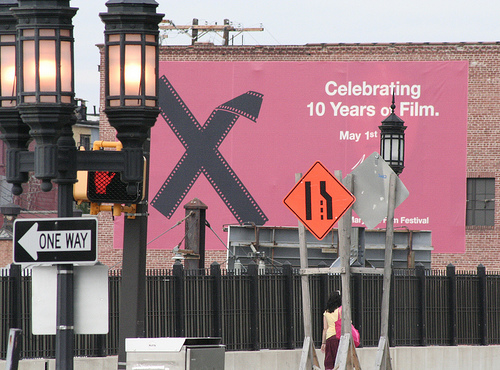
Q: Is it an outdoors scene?
A: Yes, it is outdoors.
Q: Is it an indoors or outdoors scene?
A: It is outdoors.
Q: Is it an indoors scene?
A: No, it is outdoors.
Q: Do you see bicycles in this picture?
A: No, there are no bicycles.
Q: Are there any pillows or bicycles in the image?
A: No, there are no bicycles or pillows.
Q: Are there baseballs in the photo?
A: No, there are no baseballs.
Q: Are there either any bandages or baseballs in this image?
A: No, there are no baseballs or bandages.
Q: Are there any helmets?
A: No, there are no helmets.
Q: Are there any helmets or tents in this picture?
A: No, there are no helmets or tents.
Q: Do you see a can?
A: No, there are no cans.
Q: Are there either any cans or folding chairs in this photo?
A: No, there are no cans or folding chairs.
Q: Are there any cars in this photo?
A: No, there are no cars.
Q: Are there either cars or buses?
A: No, there are no cars or buses.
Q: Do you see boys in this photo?
A: No, there are no boys.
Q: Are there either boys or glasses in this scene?
A: No, there are no boys or glasses.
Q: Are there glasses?
A: No, there are no glasses.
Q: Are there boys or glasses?
A: No, there are no glasses or boys.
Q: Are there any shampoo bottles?
A: No, there are no shampoo bottles.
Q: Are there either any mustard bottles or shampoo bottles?
A: No, there are no shampoo bottles or mustard bottles.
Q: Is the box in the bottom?
A: Yes, the box is in the bottom of the image.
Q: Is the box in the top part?
A: No, the box is in the bottom of the image.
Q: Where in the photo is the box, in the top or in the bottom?
A: The box is in the bottom of the image.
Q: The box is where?
A: The box is on the street.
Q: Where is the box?
A: The box is on the street.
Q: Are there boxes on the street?
A: Yes, there is a box on the street.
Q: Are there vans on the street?
A: No, there is a box on the street.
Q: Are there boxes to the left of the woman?
A: Yes, there is a box to the left of the woman.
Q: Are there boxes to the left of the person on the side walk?
A: Yes, there is a box to the left of the woman.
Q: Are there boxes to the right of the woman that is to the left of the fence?
A: No, the box is to the left of the woman.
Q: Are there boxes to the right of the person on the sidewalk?
A: No, the box is to the left of the woman.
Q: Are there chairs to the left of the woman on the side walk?
A: No, there is a box to the left of the woman.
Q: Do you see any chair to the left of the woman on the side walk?
A: No, there is a box to the left of the woman.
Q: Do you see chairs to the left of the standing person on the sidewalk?
A: No, there is a box to the left of the woman.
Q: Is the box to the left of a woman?
A: Yes, the box is to the left of a woman.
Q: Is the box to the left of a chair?
A: No, the box is to the left of a woman.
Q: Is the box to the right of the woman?
A: No, the box is to the left of the woman.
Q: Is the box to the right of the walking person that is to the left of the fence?
A: No, the box is to the left of the woman.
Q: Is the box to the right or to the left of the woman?
A: The box is to the left of the woman.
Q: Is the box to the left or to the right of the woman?
A: The box is to the left of the woman.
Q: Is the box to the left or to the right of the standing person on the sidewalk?
A: The box is to the left of the woman.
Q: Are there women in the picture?
A: Yes, there is a woman.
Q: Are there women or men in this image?
A: Yes, there is a woman.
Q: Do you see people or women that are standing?
A: Yes, the woman is standing.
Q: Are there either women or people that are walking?
A: Yes, the woman is walking.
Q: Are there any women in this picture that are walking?
A: Yes, there is a woman that is walking.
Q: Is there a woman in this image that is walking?
A: Yes, there is a woman that is walking.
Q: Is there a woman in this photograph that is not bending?
A: Yes, there is a woman that is walking.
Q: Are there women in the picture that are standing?
A: Yes, there is a woman that is standing.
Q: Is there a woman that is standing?
A: Yes, there is a woman that is standing.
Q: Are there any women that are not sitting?
A: Yes, there is a woman that is standing.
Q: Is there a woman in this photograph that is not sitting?
A: Yes, there is a woman that is standing.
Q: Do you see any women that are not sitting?
A: Yes, there is a woman that is standing .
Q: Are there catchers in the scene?
A: No, there are no catchers.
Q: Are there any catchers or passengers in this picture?
A: No, there are no catchers or passengers.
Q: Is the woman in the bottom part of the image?
A: Yes, the woman is in the bottom of the image.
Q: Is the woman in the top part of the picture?
A: No, the woman is in the bottom of the image.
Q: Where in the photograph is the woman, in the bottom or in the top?
A: The woman is in the bottom of the image.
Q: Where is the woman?
A: The woman is on the sidewalk.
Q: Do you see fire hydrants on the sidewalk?
A: No, there is a woman on the sidewalk.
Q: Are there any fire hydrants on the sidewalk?
A: No, there is a woman on the sidewalk.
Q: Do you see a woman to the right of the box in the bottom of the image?
A: Yes, there is a woman to the right of the box.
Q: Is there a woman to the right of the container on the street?
A: Yes, there is a woman to the right of the box.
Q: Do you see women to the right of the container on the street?
A: Yes, there is a woman to the right of the box.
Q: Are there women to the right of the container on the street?
A: Yes, there is a woman to the right of the box.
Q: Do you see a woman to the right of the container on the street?
A: Yes, there is a woman to the right of the box.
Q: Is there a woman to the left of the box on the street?
A: No, the woman is to the right of the box.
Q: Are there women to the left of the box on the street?
A: No, the woman is to the right of the box.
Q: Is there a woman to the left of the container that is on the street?
A: No, the woman is to the right of the box.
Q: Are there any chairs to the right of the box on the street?
A: No, there is a woman to the right of the box.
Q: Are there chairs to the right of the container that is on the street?
A: No, there is a woman to the right of the box.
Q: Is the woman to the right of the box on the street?
A: Yes, the woman is to the right of the box.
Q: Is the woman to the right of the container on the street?
A: Yes, the woman is to the right of the box.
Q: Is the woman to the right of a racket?
A: No, the woman is to the right of the box.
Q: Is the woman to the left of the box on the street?
A: No, the woman is to the right of the box.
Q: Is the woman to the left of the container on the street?
A: No, the woman is to the right of the box.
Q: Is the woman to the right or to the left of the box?
A: The woman is to the right of the box.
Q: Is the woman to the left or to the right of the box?
A: The woman is to the right of the box.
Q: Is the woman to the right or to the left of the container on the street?
A: The woman is to the right of the box.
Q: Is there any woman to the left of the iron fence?
A: Yes, there is a woman to the left of the fence.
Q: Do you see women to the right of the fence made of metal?
A: No, the woman is to the left of the fence.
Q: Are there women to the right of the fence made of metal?
A: No, the woman is to the left of the fence.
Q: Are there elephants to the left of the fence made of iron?
A: No, there is a woman to the left of the fence.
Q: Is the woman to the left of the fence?
A: Yes, the woman is to the left of the fence.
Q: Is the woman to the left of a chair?
A: No, the woman is to the left of the fence.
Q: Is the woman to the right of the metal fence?
A: No, the woman is to the left of the fence.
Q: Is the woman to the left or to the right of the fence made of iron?
A: The woman is to the left of the fence.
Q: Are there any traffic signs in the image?
A: Yes, there is a traffic sign.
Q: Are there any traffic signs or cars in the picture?
A: Yes, there is a traffic sign.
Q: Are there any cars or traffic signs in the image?
A: Yes, there is a traffic sign.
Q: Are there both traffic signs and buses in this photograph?
A: No, there is a traffic sign but no buses.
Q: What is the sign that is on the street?
A: The sign is a traffic sign.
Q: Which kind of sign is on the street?
A: The sign is a traffic sign.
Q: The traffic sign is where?
A: The traffic sign is on the street.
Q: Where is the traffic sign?
A: The traffic sign is on the street.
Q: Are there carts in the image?
A: No, there are no carts.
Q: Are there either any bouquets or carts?
A: No, there are no carts or bouquets.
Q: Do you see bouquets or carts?
A: No, there are no carts or bouquets.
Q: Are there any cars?
A: No, there are no cars.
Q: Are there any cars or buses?
A: No, there are no cars or buses.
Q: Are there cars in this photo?
A: No, there are no cars.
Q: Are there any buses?
A: No, there are no buses.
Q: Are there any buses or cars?
A: No, there are no buses or cars.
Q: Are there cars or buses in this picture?
A: No, there are no buses or cars.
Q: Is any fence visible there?
A: Yes, there is a fence.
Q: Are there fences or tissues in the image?
A: Yes, there is a fence.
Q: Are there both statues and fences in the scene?
A: No, there is a fence but no statues.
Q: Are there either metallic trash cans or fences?
A: Yes, there is a metal fence.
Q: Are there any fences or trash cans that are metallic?
A: Yes, the fence is metallic.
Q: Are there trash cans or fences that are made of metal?
A: Yes, the fence is made of metal.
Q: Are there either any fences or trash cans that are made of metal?
A: Yes, the fence is made of metal.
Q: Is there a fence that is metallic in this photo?
A: Yes, there is a metal fence.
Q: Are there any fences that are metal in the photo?
A: Yes, there is a metal fence.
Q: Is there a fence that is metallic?
A: Yes, there is a fence that is metallic.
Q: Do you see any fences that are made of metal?
A: Yes, there is a fence that is made of metal.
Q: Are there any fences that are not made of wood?
A: Yes, there is a fence that is made of metal.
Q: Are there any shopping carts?
A: No, there are no shopping carts.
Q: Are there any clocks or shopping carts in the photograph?
A: No, there are no shopping carts or clocks.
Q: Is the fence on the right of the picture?
A: Yes, the fence is on the right of the image.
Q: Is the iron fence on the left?
A: No, the fence is on the right of the image.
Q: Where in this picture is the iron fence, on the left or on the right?
A: The fence is on the right of the image.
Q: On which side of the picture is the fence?
A: The fence is on the right of the image.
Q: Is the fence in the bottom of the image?
A: Yes, the fence is in the bottom of the image.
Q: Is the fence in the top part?
A: No, the fence is in the bottom of the image.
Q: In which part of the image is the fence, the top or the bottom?
A: The fence is in the bottom of the image.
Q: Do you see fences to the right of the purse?
A: Yes, there is a fence to the right of the purse.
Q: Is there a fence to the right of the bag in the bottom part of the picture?
A: Yes, there is a fence to the right of the purse.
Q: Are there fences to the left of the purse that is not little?
A: No, the fence is to the right of the purse.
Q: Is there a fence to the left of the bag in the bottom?
A: No, the fence is to the right of the purse.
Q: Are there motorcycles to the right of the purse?
A: No, there is a fence to the right of the purse.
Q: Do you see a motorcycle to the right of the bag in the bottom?
A: No, there is a fence to the right of the purse.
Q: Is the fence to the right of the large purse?
A: Yes, the fence is to the right of the purse.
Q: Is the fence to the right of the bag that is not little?
A: Yes, the fence is to the right of the purse.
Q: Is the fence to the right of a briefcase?
A: No, the fence is to the right of the purse.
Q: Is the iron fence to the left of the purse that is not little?
A: No, the fence is to the right of the purse.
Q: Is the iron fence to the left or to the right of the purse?
A: The fence is to the right of the purse.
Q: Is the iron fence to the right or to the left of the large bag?
A: The fence is to the right of the purse.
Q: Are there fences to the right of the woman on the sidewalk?
A: Yes, there is a fence to the right of the woman.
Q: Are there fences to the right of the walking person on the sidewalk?
A: Yes, there is a fence to the right of the woman.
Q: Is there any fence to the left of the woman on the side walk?
A: No, the fence is to the right of the woman.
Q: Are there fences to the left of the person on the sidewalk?
A: No, the fence is to the right of the woman.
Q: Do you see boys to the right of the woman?
A: No, there is a fence to the right of the woman.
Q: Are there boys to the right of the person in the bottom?
A: No, there is a fence to the right of the woman.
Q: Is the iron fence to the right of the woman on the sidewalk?
A: Yes, the fence is to the right of the woman.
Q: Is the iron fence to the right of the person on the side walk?
A: Yes, the fence is to the right of the woman.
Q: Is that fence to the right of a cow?
A: No, the fence is to the right of the woman.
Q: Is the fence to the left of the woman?
A: No, the fence is to the right of the woman.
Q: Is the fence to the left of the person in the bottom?
A: No, the fence is to the right of the woman.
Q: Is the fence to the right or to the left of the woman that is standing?
A: The fence is to the right of the woman.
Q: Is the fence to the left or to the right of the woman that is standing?
A: The fence is to the right of the woman.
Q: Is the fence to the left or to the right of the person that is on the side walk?
A: The fence is to the right of the woman.